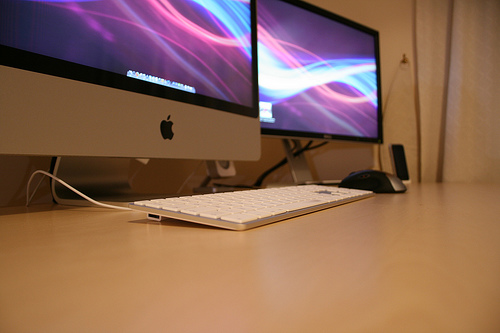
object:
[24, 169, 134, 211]
cord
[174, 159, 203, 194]
cord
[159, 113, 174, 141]
symbol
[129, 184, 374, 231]
keyboard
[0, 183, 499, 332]
table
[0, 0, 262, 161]
monitor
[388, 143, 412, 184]
speaker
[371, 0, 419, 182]
wall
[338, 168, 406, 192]
mouse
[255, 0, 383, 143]
monitor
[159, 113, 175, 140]
logo